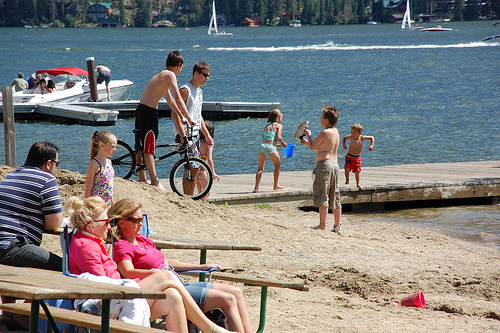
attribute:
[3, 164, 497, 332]
beach — sandy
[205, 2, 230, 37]
sail — white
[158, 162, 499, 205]
boardwalk — wooden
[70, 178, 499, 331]
sand — tan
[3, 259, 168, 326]
table — wooden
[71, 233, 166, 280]
shirt — pink, blue, striped, white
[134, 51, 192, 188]
man — sitting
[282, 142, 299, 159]
bucket — pink, blue, red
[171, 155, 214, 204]
rubber tire — black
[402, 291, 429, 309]
pail — red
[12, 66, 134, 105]
boat top — red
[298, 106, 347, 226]
boy — holding, wearing, standing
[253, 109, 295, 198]
girl — carrying, wearing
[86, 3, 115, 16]
roof — green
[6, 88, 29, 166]
post — wooden